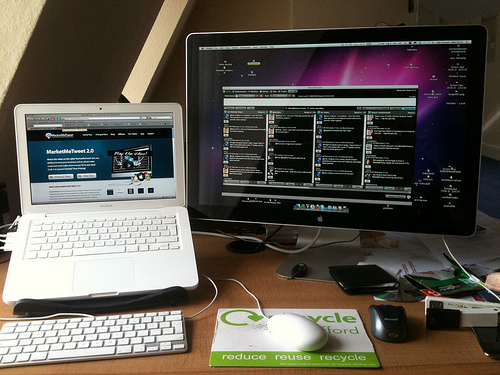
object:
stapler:
[424, 295, 498, 332]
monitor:
[176, 25, 492, 238]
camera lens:
[99, 107, 103, 111]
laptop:
[1, 102, 198, 303]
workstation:
[3, 26, 493, 373]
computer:
[185, 23, 487, 280]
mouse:
[265, 310, 329, 354]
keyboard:
[5, 303, 186, 366]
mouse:
[368, 302, 408, 343]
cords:
[220, 228, 275, 245]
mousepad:
[202, 302, 385, 371]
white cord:
[213, 275, 269, 319]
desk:
[0, 233, 495, 370]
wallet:
[327, 266, 399, 296]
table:
[0, 210, 497, 373]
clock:
[288, 263, 309, 281]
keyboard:
[16, 217, 190, 257]